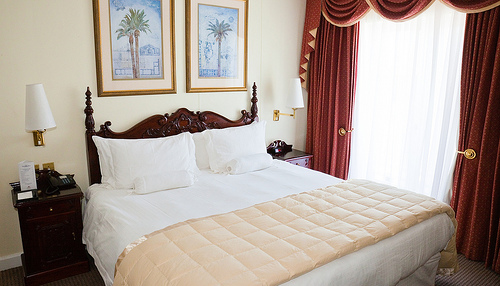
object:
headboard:
[82, 81, 259, 186]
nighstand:
[40, 173, 76, 196]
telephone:
[13, 156, 38, 202]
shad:
[21, 81, 57, 145]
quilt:
[81, 159, 460, 286]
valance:
[297, 0, 500, 92]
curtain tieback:
[455, 148, 476, 160]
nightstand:
[266, 139, 293, 158]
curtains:
[290, 0, 500, 273]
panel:
[347, 10, 469, 205]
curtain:
[299, 20, 360, 180]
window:
[342, 7, 467, 204]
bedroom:
[0, 0, 500, 286]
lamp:
[22, 83, 57, 170]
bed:
[80, 82, 459, 286]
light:
[273, 77, 304, 122]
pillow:
[91, 131, 202, 195]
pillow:
[201, 123, 275, 175]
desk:
[8, 162, 89, 285]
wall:
[0, 0, 300, 286]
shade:
[20, 84, 55, 132]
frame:
[92, 0, 176, 98]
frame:
[182, 0, 250, 94]